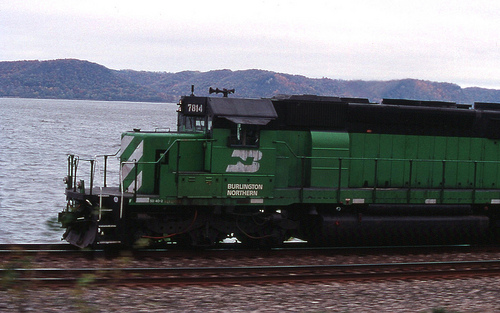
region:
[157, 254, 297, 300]
tracks under green train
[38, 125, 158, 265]
front of green train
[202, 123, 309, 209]
logo on green train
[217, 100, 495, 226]
green train driving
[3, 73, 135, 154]
waves in the back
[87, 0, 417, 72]
clear skies that are above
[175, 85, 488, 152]
black top of green train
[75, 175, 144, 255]
stairs of the train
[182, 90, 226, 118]
white number on train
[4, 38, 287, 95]
grassy hills in distance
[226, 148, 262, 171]
N and B signage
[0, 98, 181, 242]
Small body of water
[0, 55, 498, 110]
A set of hill peaks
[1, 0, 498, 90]
Cloudy and stormy looking sky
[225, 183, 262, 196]
White Burlington Northern signage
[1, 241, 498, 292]
Two sets of train tracks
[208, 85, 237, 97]
Small black train horn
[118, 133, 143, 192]
Brown and white stripes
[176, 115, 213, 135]
Small train window frames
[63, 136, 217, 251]
Silver metal hand railings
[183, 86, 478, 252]
green and black train on tracks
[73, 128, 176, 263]
green and black train on tracks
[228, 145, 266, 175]
white sign on train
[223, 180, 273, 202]
white sign on train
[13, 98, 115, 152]
blue gray water near train tracks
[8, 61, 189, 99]
low brown hills near train tracks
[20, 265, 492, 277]
grayish brown train tracks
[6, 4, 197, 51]
white and gray clouds against sky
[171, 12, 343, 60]
white and gray clouds against sky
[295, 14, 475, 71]
white and gray clouds against sky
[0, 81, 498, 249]
The train runs along the lake.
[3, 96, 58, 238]
The water is calm.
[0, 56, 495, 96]
Mountains are on the background.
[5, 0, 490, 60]
The sky is cloudy.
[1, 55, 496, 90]
Trees cover the mountains.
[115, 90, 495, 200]
The train is black and green.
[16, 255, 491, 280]
The rail tracks are not being used.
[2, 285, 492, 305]
Crushed stones are alongside the rail tracks.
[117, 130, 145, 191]
The head of the train is green and white striped.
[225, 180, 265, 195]
The "Burlington Northern" sign is painted in white.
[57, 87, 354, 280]
train on train tracks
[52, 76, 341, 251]
green train on tracks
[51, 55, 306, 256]
7814 written on top of train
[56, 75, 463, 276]
green train with black on top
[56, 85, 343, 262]
train engine that moves train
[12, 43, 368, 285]
lake behind green train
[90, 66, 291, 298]
front of train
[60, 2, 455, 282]
train is moving on tracks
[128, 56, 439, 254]
writing on side of train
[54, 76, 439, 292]
train wheels on track